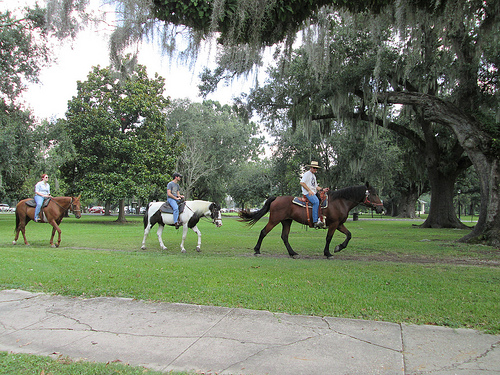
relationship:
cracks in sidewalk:
[42, 308, 244, 359] [70, 287, 316, 374]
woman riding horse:
[24, 169, 53, 223] [11, 194, 94, 254]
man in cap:
[160, 167, 187, 223] [172, 168, 186, 181]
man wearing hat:
[293, 160, 331, 227] [300, 156, 325, 170]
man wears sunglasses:
[293, 160, 331, 227] [307, 166, 323, 173]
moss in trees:
[297, 27, 350, 76] [328, 13, 496, 185]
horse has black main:
[252, 180, 388, 268] [332, 183, 367, 201]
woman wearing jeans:
[24, 169, 53, 223] [30, 195, 45, 222]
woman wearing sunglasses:
[24, 169, 53, 223] [40, 176, 53, 182]